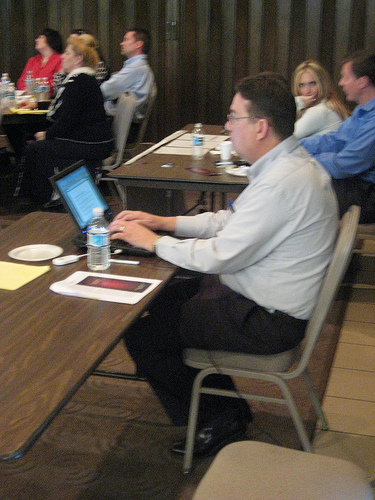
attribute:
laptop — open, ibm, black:
[55, 156, 145, 249]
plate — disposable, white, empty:
[21, 243, 62, 271]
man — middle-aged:
[151, 81, 330, 465]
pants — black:
[153, 275, 280, 424]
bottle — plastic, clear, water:
[79, 221, 121, 277]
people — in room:
[253, 45, 375, 212]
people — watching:
[31, 23, 149, 161]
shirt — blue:
[300, 94, 375, 190]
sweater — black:
[29, 61, 116, 149]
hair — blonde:
[282, 73, 359, 107]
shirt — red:
[10, 45, 68, 95]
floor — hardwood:
[86, 311, 289, 380]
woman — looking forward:
[265, 42, 360, 168]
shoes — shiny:
[172, 404, 262, 457]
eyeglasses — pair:
[223, 110, 272, 127]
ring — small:
[114, 223, 126, 233]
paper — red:
[51, 270, 157, 306]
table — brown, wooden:
[0, 211, 144, 461]